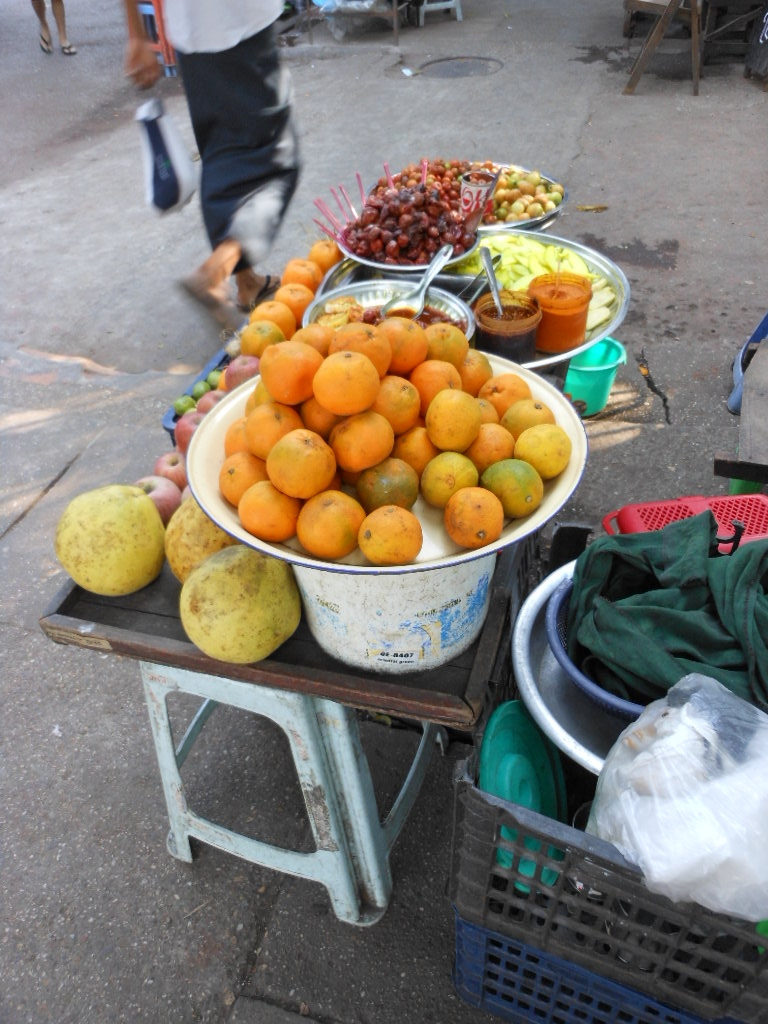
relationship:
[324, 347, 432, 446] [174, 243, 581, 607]
orange on display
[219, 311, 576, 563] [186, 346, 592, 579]
oranges on dish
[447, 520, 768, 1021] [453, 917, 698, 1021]
basket over basket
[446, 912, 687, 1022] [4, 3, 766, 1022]
basket sitting on pavement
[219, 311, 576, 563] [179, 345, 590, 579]
oranges sitting on plate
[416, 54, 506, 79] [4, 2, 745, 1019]
manhole cover placed into street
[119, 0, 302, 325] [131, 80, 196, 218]
person holding bag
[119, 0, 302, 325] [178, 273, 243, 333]
person wearing sandal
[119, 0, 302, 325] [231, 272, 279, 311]
person wearing sandal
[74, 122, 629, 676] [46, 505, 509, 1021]
fruit sitting on a bench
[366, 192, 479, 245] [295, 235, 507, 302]
cherries in a bowl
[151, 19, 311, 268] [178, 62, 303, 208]
person wearing skirt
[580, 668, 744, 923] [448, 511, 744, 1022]
bag lying inside crate